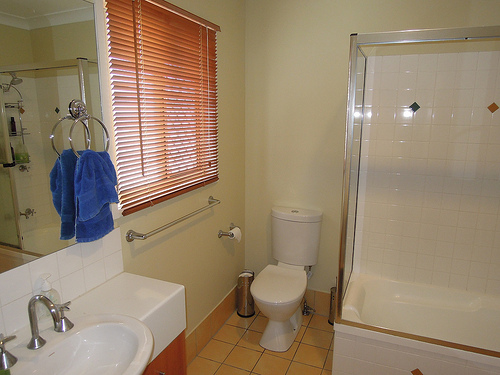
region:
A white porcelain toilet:
[243, 185, 328, 360]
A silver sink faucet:
[17, 284, 63, 356]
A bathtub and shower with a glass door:
[318, 13, 498, 371]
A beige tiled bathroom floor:
[210, 337, 257, 372]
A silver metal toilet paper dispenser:
[212, 216, 244, 250]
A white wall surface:
[255, 48, 334, 188]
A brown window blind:
[104, 27, 232, 213]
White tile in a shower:
[393, 133, 492, 270]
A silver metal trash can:
[230, 260, 257, 327]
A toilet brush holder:
[322, 268, 342, 330]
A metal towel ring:
[64, 99, 114, 154]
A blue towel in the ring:
[71, 147, 121, 241]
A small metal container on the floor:
[234, 265, 257, 319]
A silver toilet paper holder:
[219, 222, 241, 240]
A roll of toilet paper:
[227, 225, 243, 242]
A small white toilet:
[249, 202, 323, 350]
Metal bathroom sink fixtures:
[3, 294, 76, 371]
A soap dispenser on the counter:
[35, 274, 64, 314]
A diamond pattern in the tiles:
[407, 99, 422, 113]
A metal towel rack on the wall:
[120, 196, 222, 243]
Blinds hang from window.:
[102, 0, 220, 217]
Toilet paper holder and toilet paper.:
[219, 224, 244, 241]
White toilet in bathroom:
[246, 204, 322, 353]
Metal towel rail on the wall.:
[126, 193, 230, 248]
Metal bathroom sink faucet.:
[22, 293, 62, 349]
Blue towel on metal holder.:
[75, 149, 115, 241]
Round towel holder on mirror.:
[67, 100, 112, 157]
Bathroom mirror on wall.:
[0, 35, 113, 272]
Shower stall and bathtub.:
[331, 35, 498, 373]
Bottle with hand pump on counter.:
[28, 271, 75, 315]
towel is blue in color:
[63, 163, 118, 210]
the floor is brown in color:
[242, 350, 296, 372]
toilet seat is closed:
[253, 267, 299, 354]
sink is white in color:
[49, 314, 171, 374]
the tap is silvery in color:
[24, 296, 66, 336]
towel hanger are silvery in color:
[60, 110, 105, 145]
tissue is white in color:
[228, 228, 252, 239]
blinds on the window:
[101, 0, 227, 215]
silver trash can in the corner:
[233, 267, 258, 322]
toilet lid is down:
[248, 258, 307, 315]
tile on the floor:
[173, 296, 342, 373]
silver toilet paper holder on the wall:
[219, 220, 244, 245]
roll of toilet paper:
[228, 225, 245, 244]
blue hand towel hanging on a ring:
[61, 100, 129, 250]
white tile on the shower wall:
[338, 57, 498, 319]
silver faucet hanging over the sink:
[21, 289, 80, 357]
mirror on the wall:
[1, 0, 121, 277]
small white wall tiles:
[378, 53, 402, 73]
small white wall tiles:
[394, 48, 422, 81]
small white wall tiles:
[411, 50, 443, 77]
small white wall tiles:
[433, 48, 462, 78]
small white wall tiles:
[471, 45, 499, 80]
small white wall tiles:
[373, 67, 402, 94]